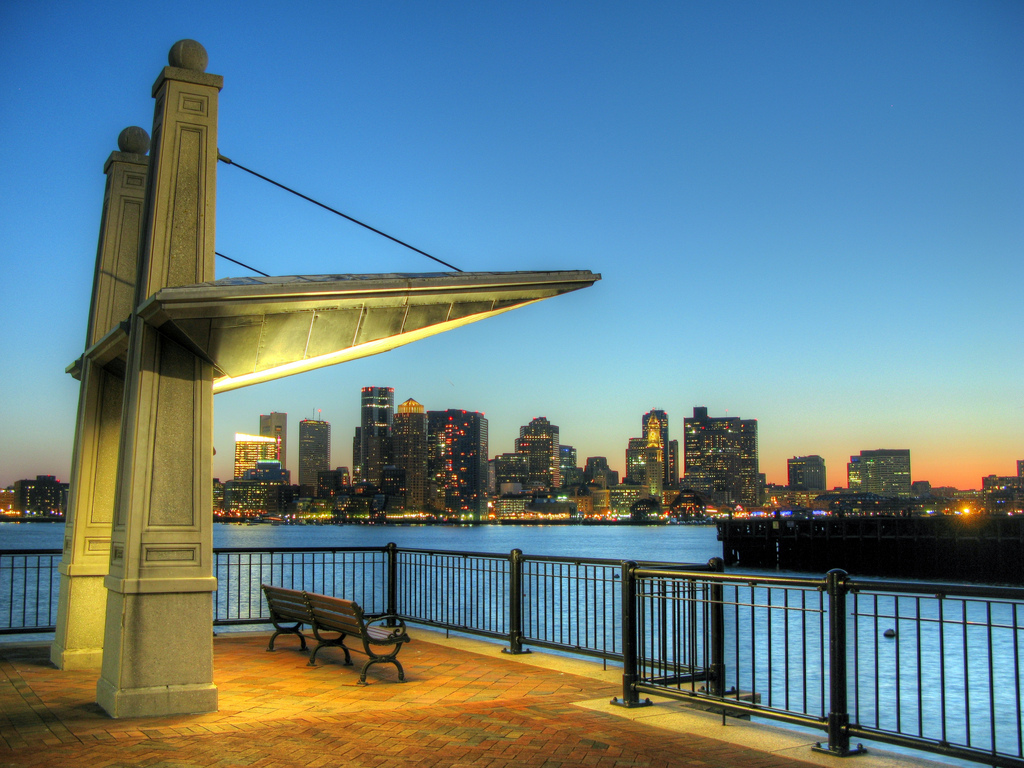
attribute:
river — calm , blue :
[6, 482, 1016, 757]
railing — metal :
[6, 507, 1018, 758]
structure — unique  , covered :
[60, 30, 629, 756]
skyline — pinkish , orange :
[0, 430, 1018, 513]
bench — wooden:
[261, 531, 439, 678]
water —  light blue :
[525, 540, 698, 683]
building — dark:
[404, 434, 467, 530]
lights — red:
[437, 427, 472, 495]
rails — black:
[248, 533, 1022, 657]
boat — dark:
[676, 449, 1022, 627]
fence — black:
[316, 552, 952, 741]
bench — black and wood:
[227, 540, 441, 720]